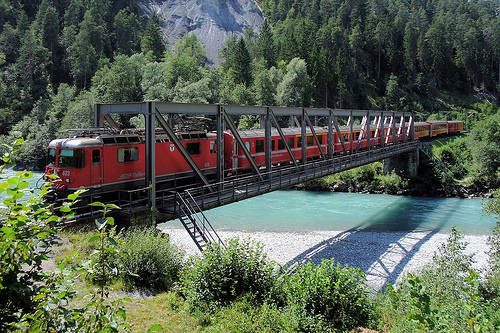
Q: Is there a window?
A: Yes, there is a window.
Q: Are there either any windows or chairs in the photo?
A: Yes, there is a window.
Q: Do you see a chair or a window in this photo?
A: Yes, there is a window.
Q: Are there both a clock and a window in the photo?
A: No, there is a window but no clocks.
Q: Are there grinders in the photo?
A: No, there are no grinders.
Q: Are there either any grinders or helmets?
A: No, there are no grinders or helmets.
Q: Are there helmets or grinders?
A: No, there are no grinders or helmets.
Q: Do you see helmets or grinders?
A: No, there are no grinders or helmets.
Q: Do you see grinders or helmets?
A: No, there are no grinders or helmets.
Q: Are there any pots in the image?
A: No, there are no pots.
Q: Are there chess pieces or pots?
A: No, there are no pots or chess pieces.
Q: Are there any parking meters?
A: No, there are no parking meters.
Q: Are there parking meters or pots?
A: No, there are no parking meters or pots.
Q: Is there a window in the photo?
A: Yes, there is a window.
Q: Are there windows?
A: Yes, there is a window.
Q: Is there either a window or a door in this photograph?
A: Yes, there is a window.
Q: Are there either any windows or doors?
A: Yes, there is a window.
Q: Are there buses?
A: No, there are no buses.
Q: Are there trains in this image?
A: Yes, there is a train.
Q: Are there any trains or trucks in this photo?
A: Yes, there is a train.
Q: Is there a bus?
A: No, there are no buses.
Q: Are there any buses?
A: No, there are no buses.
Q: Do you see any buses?
A: No, there are no buses.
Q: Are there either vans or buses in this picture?
A: No, there are no buses or vans.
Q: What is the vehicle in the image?
A: The vehicle is a train.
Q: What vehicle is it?
A: The vehicle is a train.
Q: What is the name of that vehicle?
A: This is a train.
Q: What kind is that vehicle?
A: This is a train.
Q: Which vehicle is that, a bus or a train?
A: This is a train.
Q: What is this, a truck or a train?
A: This is a train.